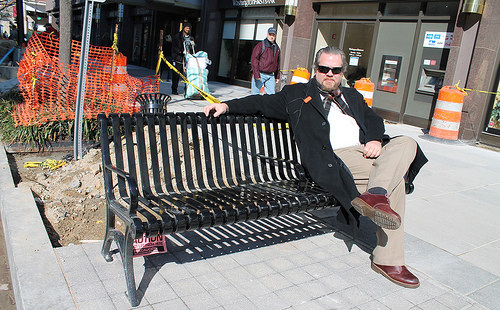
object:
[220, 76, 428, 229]
coat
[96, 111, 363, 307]
bench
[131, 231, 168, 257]
paper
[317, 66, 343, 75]
glasses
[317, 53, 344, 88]
face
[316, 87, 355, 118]
scarf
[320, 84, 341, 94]
neck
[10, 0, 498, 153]
building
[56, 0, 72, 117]
tree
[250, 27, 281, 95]
man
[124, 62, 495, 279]
sidewalk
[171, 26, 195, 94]
man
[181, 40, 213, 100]
cart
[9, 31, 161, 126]
barricade fencing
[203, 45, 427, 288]
guy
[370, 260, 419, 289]
shoe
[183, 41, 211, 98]
luggage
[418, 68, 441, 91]
atm machine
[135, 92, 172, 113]
trash can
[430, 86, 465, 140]
cone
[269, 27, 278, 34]
cap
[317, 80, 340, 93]
beard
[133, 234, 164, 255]
writing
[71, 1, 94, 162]
sign pole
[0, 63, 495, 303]
pavement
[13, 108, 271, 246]
section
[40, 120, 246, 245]
dirt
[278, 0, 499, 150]
wall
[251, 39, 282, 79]
coat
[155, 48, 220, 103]
caution tape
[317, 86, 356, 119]
cravat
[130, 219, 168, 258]
caution sign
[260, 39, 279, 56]
backpack